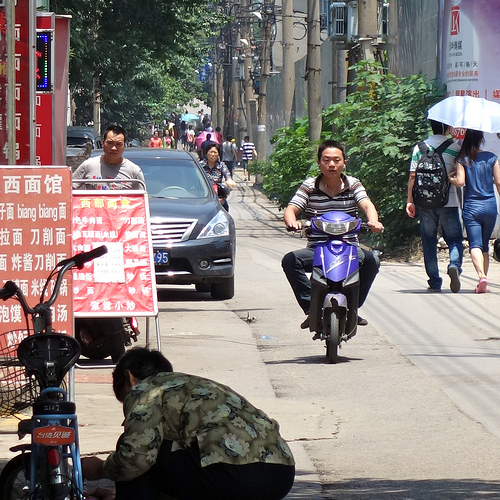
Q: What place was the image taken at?
A: It was taken at the street.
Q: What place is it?
A: It is a street.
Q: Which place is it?
A: It is a street.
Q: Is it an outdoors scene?
A: Yes, it is outdoors.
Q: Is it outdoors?
A: Yes, it is outdoors.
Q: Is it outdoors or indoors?
A: It is outdoors.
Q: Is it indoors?
A: No, it is outdoors.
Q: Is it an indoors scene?
A: No, it is outdoors.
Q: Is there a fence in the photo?
A: No, there are no fences.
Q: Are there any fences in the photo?
A: No, there are no fences.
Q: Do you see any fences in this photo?
A: No, there are no fences.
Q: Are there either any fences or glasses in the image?
A: No, there are no fences or glasses.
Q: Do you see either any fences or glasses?
A: No, there are no fences or glasses.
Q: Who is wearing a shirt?
A: The man is wearing a shirt.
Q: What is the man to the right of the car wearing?
A: The man is wearing a shirt.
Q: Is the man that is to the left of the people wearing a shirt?
A: Yes, the man is wearing a shirt.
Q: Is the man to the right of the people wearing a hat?
A: No, the man is wearing a shirt.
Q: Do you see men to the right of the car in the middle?
A: Yes, there is a man to the right of the car.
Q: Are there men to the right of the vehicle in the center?
A: Yes, there is a man to the right of the car.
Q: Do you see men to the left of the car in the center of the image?
A: No, the man is to the right of the car.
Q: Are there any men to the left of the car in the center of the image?
A: No, the man is to the right of the car.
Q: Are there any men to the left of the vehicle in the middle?
A: No, the man is to the right of the car.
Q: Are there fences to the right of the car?
A: No, there is a man to the right of the car.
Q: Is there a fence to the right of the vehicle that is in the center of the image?
A: No, there is a man to the right of the car.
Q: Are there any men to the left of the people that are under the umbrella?
A: Yes, there is a man to the left of the people.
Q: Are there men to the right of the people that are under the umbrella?
A: No, the man is to the left of the people.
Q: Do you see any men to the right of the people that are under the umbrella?
A: No, the man is to the left of the people.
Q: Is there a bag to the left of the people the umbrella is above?
A: No, there is a man to the left of the people.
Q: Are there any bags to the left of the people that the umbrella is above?
A: No, there is a man to the left of the people.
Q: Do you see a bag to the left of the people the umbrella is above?
A: No, there is a man to the left of the people.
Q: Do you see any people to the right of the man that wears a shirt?
A: Yes, there is a person to the right of the man.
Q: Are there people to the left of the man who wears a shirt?
A: No, the person is to the right of the man.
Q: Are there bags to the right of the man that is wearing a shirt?
A: No, there is a person to the right of the man.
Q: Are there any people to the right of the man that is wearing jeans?
A: Yes, there is a person to the right of the man.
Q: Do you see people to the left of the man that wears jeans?
A: No, the person is to the right of the man.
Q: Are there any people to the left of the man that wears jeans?
A: No, the person is to the right of the man.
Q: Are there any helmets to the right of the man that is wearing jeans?
A: No, there is a person to the right of the man.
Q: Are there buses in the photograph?
A: No, there are no buses.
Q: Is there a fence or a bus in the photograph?
A: No, there are no buses or fences.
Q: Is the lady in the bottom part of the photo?
A: Yes, the lady is in the bottom of the image.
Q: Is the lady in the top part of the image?
A: No, the lady is in the bottom of the image.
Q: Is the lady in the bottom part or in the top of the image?
A: The lady is in the bottom of the image.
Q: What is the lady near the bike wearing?
A: The lady is wearing a shirt.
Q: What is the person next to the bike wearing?
A: The lady is wearing a shirt.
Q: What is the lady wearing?
A: The lady is wearing a shirt.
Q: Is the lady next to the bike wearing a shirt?
A: Yes, the lady is wearing a shirt.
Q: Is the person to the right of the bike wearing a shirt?
A: Yes, the lady is wearing a shirt.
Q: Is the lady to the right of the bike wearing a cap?
A: No, the lady is wearing a shirt.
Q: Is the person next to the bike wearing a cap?
A: No, the lady is wearing a shirt.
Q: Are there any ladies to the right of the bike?
A: Yes, there is a lady to the right of the bike.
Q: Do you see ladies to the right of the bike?
A: Yes, there is a lady to the right of the bike.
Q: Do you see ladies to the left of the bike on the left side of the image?
A: No, the lady is to the right of the bike.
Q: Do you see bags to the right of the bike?
A: No, there is a lady to the right of the bike.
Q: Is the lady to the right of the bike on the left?
A: Yes, the lady is to the right of the bike.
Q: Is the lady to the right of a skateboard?
A: No, the lady is to the right of the bike.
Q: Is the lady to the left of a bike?
A: No, the lady is to the right of a bike.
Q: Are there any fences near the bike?
A: No, there is a lady near the bike.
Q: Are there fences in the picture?
A: No, there are no fences.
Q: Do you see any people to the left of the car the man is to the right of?
A: Yes, there are people to the left of the car.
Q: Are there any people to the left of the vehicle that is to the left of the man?
A: Yes, there are people to the left of the car.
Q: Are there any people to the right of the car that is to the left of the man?
A: No, the people are to the left of the car.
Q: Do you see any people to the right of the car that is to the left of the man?
A: No, the people are to the left of the car.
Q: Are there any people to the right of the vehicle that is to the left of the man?
A: No, the people are to the left of the car.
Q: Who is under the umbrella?
A: The people are under the umbrella.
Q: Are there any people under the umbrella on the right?
A: Yes, there are people under the umbrella.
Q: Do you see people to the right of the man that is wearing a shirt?
A: Yes, there are people to the right of the man.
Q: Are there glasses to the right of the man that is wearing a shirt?
A: No, there are people to the right of the man.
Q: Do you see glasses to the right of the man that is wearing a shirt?
A: No, there are people to the right of the man.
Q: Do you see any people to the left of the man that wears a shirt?
A: Yes, there are people to the left of the man.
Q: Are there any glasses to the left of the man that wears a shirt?
A: No, there are people to the left of the man.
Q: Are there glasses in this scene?
A: No, there are no glasses.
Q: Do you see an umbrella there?
A: Yes, there is an umbrella.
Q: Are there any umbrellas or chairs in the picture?
A: Yes, there is an umbrella.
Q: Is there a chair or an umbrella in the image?
A: Yes, there is an umbrella.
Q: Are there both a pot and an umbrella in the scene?
A: No, there is an umbrella but no pots.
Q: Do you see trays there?
A: No, there are no trays.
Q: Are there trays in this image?
A: No, there are no trays.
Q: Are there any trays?
A: No, there are no trays.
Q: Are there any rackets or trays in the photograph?
A: No, there are no trays or rackets.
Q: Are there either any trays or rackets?
A: No, there are no trays or rackets.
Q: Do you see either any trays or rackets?
A: No, there are no trays or rackets.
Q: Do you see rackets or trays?
A: No, there are no trays or rackets.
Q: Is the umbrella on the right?
A: Yes, the umbrella is on the right of the image.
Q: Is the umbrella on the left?
A: No, the umbrella is on the right of the image.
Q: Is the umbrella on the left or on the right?
A: The umbrella is on the right of the image.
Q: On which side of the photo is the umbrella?
A: The umbrella is on the right of the image.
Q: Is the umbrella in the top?
A: Yes, the umbrella is in the top of the image.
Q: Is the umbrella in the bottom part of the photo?
A: No, the umbrella is in the top of the image.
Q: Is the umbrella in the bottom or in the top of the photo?
A: The umbrella is in the top of the image.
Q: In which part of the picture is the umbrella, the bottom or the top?
A: The umbrella is in the top of the image.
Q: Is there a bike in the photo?
A: Yes, there is a bike.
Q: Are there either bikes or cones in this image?
A: Yes, there is a bike.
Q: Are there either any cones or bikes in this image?
A: Yes, there is a bike.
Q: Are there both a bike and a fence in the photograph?
A: No, there is a bike but no fences.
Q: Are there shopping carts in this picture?
A: No, there are no shopping carts.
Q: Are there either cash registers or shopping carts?
A: No, there are no shopping carts or cash registers.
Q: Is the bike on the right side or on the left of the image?
A: The bike is on the left of the image.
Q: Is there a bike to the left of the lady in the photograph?
A: Yes, there is a bike to the left of the lady.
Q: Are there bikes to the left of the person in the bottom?
A: Yes, there is a bike to the left of the lady.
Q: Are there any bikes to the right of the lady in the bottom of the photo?
A: No, the bike is to the left of the lady.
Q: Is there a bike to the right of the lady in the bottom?
A: No, the bike is to the left of the lady.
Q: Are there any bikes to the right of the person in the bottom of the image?
A: No, the bike is to the left of the lady.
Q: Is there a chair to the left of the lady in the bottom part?
A: No, there is a bike to the left of the lady.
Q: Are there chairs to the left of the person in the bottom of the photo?
A: No, there is a bike to the left of the lady.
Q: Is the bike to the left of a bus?
A: No, the bike is to the left of the lady.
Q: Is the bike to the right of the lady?
A: No, the bike is to the left of the lady.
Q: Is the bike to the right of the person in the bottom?
A: No, the bike is to the left of the lady.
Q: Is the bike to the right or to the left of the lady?
A: The bike is to the left of the lady.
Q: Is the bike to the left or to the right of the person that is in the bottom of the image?
A: The bike is to the left of the lady.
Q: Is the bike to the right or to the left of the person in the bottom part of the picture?
A: The bike is to the left of the lady.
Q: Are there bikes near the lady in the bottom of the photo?
A: Yes, there is a bike near the lady.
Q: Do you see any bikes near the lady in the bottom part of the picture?
A: Yes, there is a bike near the lady.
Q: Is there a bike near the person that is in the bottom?
A: Yes, there is a bike near the lady.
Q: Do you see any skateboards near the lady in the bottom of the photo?
A: No, there is a bike near the lady.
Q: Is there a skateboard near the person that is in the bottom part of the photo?
A: No, there is a bike near the lady.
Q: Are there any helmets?
A: No, there are no helmets.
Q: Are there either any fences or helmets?
A: No, there are no helmets or fences.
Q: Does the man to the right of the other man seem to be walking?
A: Yes, the man is walking.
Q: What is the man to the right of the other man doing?
A: The man is walking.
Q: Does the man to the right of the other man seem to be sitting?
A: No, the man is walking.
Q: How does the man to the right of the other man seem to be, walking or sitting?
A: The man is walking.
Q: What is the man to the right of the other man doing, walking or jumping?
A: The man is walking.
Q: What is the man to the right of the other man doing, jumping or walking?
A: The man is walking.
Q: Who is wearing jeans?
A: The man is wearing jeans.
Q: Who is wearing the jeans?
A: The man is wearing jeans.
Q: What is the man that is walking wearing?
A: The man is wearing jeans.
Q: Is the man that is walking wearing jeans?
A: Yes, the man is wearing jeans.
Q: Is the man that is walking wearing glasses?
A: No, the man is wearing jeans.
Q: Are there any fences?
A: No, there are no fences.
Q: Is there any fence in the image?
A: No, there are no fences.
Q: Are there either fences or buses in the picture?
A: No, there are no fences or buses.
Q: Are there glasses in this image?
A: No, there are no glasses.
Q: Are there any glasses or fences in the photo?
A: No, there are no glasses or fences.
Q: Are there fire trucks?
A: No, there are no fire trucks.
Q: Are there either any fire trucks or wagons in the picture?
A: No, there are no fire trucks or wagons.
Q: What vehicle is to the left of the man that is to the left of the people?
A: The vehicle is a car.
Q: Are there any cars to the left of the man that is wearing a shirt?
A: Yes, there is a car to the left of the man.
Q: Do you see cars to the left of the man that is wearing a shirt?
A: Yes, there is a car to the left of the man.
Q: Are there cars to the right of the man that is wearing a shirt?
A: No, the car is to the left of the man.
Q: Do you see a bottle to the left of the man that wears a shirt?
A: No, there is a car to the left of the man.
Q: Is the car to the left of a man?
A: Yes, the car is to the left of a man.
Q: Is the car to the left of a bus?
A: No, the car is to the left of a man.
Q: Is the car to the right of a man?
A: No, the car is to the left of a man.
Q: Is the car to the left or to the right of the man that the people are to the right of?
A: The car is to the left of the man.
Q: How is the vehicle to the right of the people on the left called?
A: The vehicle is a car.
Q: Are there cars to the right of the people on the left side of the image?
A: Yes, there is a car to the right of the people.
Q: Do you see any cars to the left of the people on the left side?
A: No, the car is to the right of the people.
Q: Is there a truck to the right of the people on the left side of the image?
A: No, there is a car to the right of the people.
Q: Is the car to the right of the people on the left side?
A: Yes, the car is to the right of the people.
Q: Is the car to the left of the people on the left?
A: No, the car is to the right of the people.